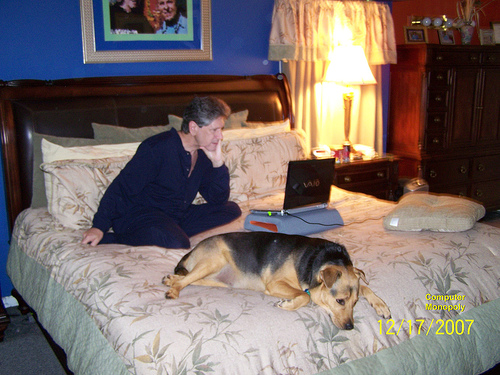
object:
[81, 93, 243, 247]
man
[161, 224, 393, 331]
dog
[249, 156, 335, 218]
laptop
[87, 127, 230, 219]
pajamas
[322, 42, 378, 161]
lamp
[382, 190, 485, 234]
cushion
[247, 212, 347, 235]
stand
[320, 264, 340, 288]
ears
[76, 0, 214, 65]
picture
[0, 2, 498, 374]
photo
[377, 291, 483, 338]
taken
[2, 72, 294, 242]
frame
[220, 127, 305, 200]
pillow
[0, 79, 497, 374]
bed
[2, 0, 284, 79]
wall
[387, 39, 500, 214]
armoire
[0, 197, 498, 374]
valence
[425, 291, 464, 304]
computer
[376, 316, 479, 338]
date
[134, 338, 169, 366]
pattern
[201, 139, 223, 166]
hand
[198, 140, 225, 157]
chin